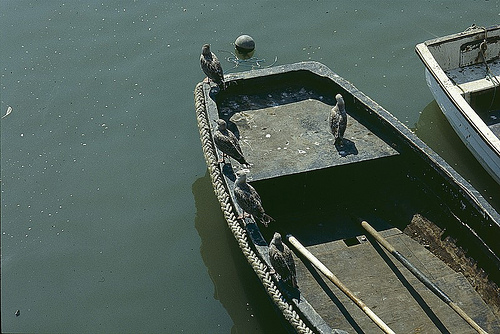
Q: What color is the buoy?
A: Black.